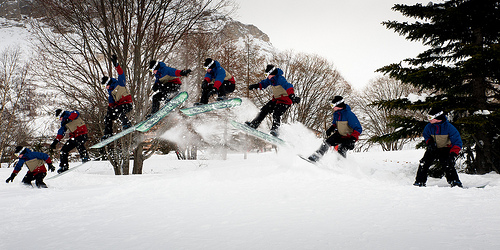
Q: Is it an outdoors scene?
A: Yes, it is outdoors.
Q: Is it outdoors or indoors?
A: It is outdoors.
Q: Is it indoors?
A: No, it is outdoors.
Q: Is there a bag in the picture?
A: No, there are no bags.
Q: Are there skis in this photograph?
A: No, there are no skis.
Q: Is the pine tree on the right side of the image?
A: Yes, the pine tree is on the right of the image.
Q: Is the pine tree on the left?
A: No, the pine tree is on the right of the image.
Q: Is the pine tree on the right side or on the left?
A: The pine tree is on the right of the image.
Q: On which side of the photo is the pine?
A: The pine is on the right of the image.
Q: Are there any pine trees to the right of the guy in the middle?
A: Yes, there is a pine tree to the right of the guy.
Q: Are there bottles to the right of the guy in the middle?
A: No, there is a pine tree to the right of the guy.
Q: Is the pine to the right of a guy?
A: Yes, the pine is to the right of a guy.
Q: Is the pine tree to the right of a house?
A: No, the pine tree is to the right of a guy.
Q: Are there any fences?
A: No, there are no fences.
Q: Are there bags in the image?
A: No, there are no bags.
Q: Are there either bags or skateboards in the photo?
A: No, there are no bags or skateboards.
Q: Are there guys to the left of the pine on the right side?
A: Yes, there is a guy to the left of the pine tree.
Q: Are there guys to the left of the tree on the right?
A: Yes, there is a guy to the left of the pine tree.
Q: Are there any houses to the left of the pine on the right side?
A: No, there is a guy to the left of the pine tree.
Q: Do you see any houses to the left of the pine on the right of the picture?
A: No, there is a guy to the left of the pine tree.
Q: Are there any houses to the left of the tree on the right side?
A: No, there is a guy to the left of the pine tree.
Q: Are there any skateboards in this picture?
A: No, there are no skateboards.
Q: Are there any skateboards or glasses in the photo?
A: No, there are no skateboards or glasses.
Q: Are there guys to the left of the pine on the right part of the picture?
A: Yes, there is a guy to the left of the pine tree.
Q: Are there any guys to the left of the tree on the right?
A: Yes, there is a guy to the left of the pine tree.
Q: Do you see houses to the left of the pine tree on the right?
A: No, there is a guy to the left of the pine tree.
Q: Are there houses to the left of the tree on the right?
A: No, there is a guy to the left of the pine tree.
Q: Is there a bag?
A: No, there are no bags.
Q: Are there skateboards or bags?
A: No, there are no bags or skateboards.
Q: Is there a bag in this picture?
A: No, there are no bags.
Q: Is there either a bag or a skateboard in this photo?
A: No, there are no bags or skateboards.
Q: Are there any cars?
A: No, there are no cars.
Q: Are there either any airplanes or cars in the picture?
A: No, there are no cars or airplanes.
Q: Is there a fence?
A: No, there are no fences.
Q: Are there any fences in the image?
A: No, there are no fences.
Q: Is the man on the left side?
A: Yes, the man is on the left of the image.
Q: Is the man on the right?
A: No, the man is on the left of the image.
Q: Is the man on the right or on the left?
A: The man is on the left of the image.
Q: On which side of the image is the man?
A: The man is on the left of the image.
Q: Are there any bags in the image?
A: No, there are no bags.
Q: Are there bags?
A: No, there are no bags.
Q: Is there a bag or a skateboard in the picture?
A: No, there are no bags or skateboards.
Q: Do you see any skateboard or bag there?
A: No, there are no bags or skateboards.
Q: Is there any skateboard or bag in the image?
A: No, there are no bags or skateboards.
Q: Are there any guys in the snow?
A: Yes, there is a guy in the snow.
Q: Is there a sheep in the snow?
A: No, there is a guy in the snow.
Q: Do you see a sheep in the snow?
A: No, there is a guy in the snow.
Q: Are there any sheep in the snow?
A: No, there is a guy in the snow.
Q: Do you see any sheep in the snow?
A: No, there is a guy in the snow.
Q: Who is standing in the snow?
A: The guy is standing in the snow.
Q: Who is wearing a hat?
A: The guy is wearing a hat.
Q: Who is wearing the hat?
A: The guy is wearing a hat.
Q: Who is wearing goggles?
A: The guy is wearing goggles.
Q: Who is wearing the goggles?
A: The guy is wearing goggles.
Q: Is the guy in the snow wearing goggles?
A: Yes, the guy is wearing goggles.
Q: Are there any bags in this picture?
A: No, there are no bags.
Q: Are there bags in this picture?
A: No, there are no bags.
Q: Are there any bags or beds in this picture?
A: No, there are no bags or beds.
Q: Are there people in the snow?
A: Yes, there is a person in the snow.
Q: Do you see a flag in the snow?
A: No, there is a person in the snow.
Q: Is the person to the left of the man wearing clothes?
A: Yes, the person is wearing clothes.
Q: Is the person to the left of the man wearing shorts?
A: No, the person is wearing clothes.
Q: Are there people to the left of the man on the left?
A: Yes, there is a person to the left of the man.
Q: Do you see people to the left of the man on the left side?
A: Yes, there is a person to the left of the man.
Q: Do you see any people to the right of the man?
A: No, the person is to the left of the man.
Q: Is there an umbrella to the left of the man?
A: No, there is a person to the left of the man.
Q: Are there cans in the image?
A: No, there are no cans.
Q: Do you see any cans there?
A: No, there are no cans.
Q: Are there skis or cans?
A: No, there are no cans or skis.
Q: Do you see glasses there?
A: No, there are no glasses.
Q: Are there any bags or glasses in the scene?
A: No, there are no glasses or bags.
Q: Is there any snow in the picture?
A: Yes, there is snow.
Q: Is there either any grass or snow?
A: Yes, there is snow.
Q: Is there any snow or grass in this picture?
A: Yes, there is snow.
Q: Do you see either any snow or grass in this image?
A: Yes, there is snow.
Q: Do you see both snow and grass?
A: No, there is snow but no grass.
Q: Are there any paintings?
A: No, there are no paintings.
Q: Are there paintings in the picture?
A: No, there are no paintings.